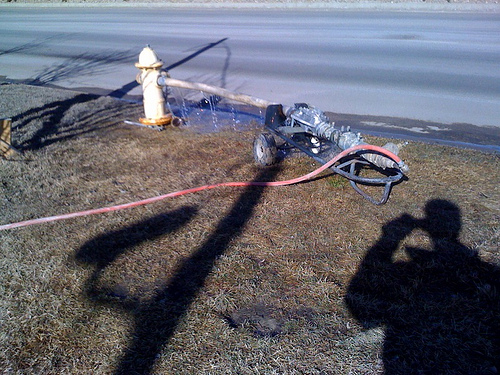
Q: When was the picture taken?
A: Daytime.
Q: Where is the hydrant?
A: Left of the picture.